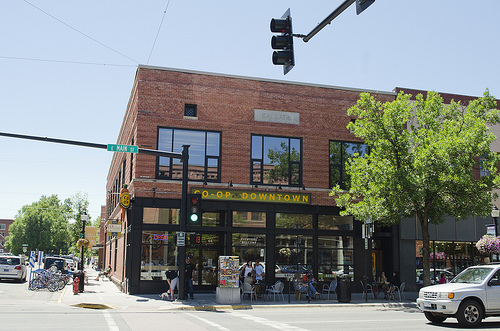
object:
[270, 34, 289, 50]
light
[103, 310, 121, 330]
line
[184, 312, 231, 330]
line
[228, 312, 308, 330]
line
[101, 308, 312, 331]
crosswalk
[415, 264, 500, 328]
vehicle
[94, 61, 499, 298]
building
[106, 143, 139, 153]
street sign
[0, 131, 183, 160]
pole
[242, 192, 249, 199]
d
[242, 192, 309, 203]
downtown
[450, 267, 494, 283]
windshield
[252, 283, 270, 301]
table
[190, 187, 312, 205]
sign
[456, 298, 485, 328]
wheel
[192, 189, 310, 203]
banner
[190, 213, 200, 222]
light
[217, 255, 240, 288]
display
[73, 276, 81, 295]
hydrant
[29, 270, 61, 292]
bicycles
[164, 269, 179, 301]
man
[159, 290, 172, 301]
dog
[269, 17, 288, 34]
light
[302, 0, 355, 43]
pole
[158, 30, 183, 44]
clouds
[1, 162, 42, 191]
white clouds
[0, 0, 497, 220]
blue sky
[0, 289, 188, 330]
intersection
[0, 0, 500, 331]
area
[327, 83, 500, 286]
tree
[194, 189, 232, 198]
co-op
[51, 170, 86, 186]
clouds